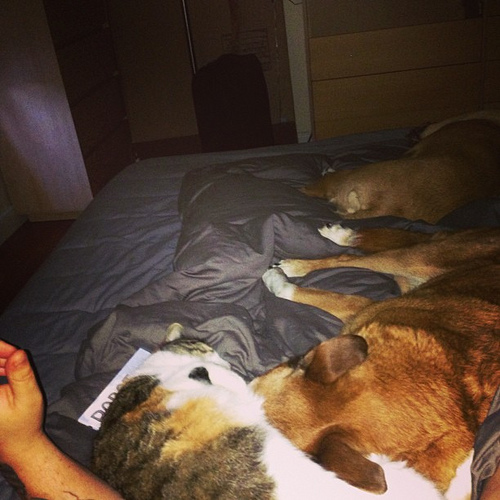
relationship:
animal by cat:
[247, 223, 500, 496] [91, 319, 473, 498]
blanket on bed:
[0, 146, 499, 498] [2, 113, 499, 498]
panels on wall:
[26, 7, 141, 179] [282, 5, 318, 133]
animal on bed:
[299, 112, 500, 224] [2, 113, 499, 498]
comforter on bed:
[66, 135, 472, 499] [2, 113, 499, 498]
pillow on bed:
[37, 291, 362, 449] [2, 113, 499, 498]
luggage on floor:
[189, 53, 275, 153] [2, 125, 298, 339]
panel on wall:
[304, 16, 500, 140] [0, 3, 497, 220]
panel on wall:
[304, 65, 499, 144] [0, 3, 497, 220]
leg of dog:
[264, 259, 371, 333] [179, 235, 499, 495]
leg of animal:
[273, 244, 420, 288] [247, 223, 500, 496]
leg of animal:
[313, 217, 413, 249] [247, 223, 500, 496]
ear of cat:
[162, 323, 182, 343] [91, 319, 473, 498]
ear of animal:
[299, 334, 372, 382] [247, 223, 500, 496]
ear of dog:
[313, 440, 387, 493] [261, 317, 498, 466]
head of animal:
[246, 325, 406, 497] [247, 223, 500, 496]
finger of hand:
[3, 332, 18, 375] [2, 333, 46, 472]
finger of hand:
[0, 323, 23, 354] [4, 345, 44, 472]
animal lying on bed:
[299, 112, 500, 224] [2, 113, 499, 498]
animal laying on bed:
[90, 322, 445, 499] [60, 144, 485, 465]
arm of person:
[1, 349, 89, 494] [4, 346, 105, 498]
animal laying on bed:
[247, 223, 500, 496] [2, 113, 499, 498]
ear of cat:
[197, 328, 218, 348] [91, 319, 473, 498]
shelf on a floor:
[0, 1, 135, 225] [1, 116, 298, 313]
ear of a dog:
[313, 440, 387, 493] [226, 214, 492, 498]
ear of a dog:
[299, 334, 368, 382] [226, 214, 492, 498]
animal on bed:
[313, 145, 499, 226] [2, 113, 499, 498]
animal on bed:
[247, 290, 497, 479] [2, 113, 499, 498]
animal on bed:
[90, 322, 430, 499] [2, 113, 499, 498]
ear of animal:
[299, 334, 368, 382] [247, 223, 500, 496]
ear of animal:
[313, 432, 386, 492] [247, 223, 500, 496]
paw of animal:
[317, 222, 357, 248] [247, 223, 500, 496]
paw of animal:
[273, 254, 306, 277] [247, 223, 500, 496]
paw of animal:
[258, 269, 300, 299] [247, 223, 500, 496]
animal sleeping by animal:
[90, 322, 445, 499] [247, 223, 500, 496]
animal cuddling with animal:
[90, 322, 445, 499] [247, 223, 500, 496]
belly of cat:
[236, 402, 324, 496] [95, 323, 425, 498]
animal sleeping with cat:
[247, 223, 500, 496] [118, 321, 270, 487]